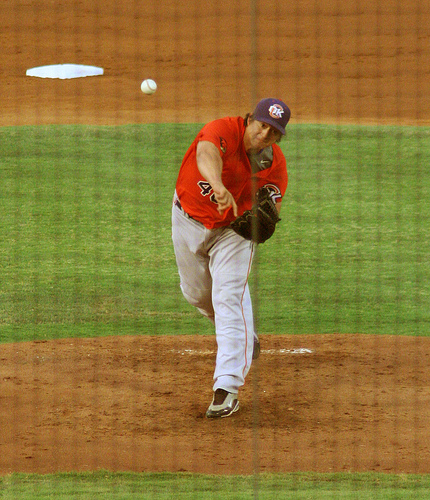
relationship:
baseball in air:
[137, 72, 160, 102] [110, 54, 201, 111]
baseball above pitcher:
[137, 72, 160, 102] [176, 100, 292, 424]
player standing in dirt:
[176, 100, 292, 424] [29, 350, 388, 455]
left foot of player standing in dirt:
[202, 365, 251, 423] [29, 350, 388, 455]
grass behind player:
[4, 133, 146, 253] [176, 100, 292, 424]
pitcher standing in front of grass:
[176, 100, 292, 424] [4, 133, 146, 253]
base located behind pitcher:
[29, 60, 107, 91] [176, 100, 292, 424]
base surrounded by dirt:
[29, 60, 107, 91] [25, 15, 426, 107]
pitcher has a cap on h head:
[176, 100, 292, 424] [242, 100, 295, 152]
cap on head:
[258, 102, 291, 134] [242, 100, 295, 152]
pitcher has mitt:
[176, 100, 292, 424] [234, 199, 282, 244]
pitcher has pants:
[176, 100, 292, 424] [172, 202, 256, 393]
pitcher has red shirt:
[176, 100, 292, 424] [175, 120, 287, 222]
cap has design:
[258, 102, 291, 134] [269, 105, 288, 124]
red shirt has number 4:
[175, 120, 287, 222] [197, 176, 210, 198]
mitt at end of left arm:
[234, 199, 282, 244] [262, 152, 289, 227]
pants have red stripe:
[172, 202, 256, 393] [239, 237, 261, 380]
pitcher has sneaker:
[176, 100, 292, 424] [208, 376, 242, 421]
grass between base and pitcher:
[4, 133, 146, 253] [176, 100, 292, 424]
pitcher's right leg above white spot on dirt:
[171, 212, 216, 321] [29, 350, 388, 455]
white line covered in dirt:
[262, 343, 313, 364] [29, 350, 388, 455]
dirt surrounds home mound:
[25, 15, 426, 107] [29, 60, 107, 91]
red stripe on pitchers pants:
[239, 237, 261, 380] [172, 202, 256, 393]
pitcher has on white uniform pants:
[176, 100, 292, 424] [172, 202, 256, 393]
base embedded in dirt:
[29, 60, 107, 91] [25, 15, 426, 107]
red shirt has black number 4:
[175, 120, 287, 222] [197, 180, 213, 197]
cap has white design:
[258, 102, 291, 134] [269, 105, 288, 124]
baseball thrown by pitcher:
[140, 77, 158, 95] [176, 100, 292, 424]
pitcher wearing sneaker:
[176, 100, 292, 424] [204, 388, 240, 420]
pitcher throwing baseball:
[176, 100, 292, 424] [137, 72, 160, 102]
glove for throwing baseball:
[234, 199, 282, 244] [137, 72, 160, 102]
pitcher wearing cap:
[176, 100, 292, 424] [258, 102, 291, 134]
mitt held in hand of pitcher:
[234, 199, 282, 244] [176, 100, 292, 424]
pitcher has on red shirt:
[176, 100, 292, 424] [175, 120, 287, 222]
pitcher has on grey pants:
[176, 100, 292, 424] [172, 202, 256, 393]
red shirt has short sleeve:
[175, 120, 287, 222] [200, 118, 241, 156]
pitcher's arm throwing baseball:
[194, 130, 238, 225] [137, 72, 160, 102]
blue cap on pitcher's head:
[258, 102, 291, 134] [242, 100, 295, 152]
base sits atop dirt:
[29, 60, 107, 91] [25, 15, 426, 107]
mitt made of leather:
[234, 199, 282, 244] [235, 204, 277, 242]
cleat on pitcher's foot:
[254, 334, 263, 362] [241, 335, 268, 363]